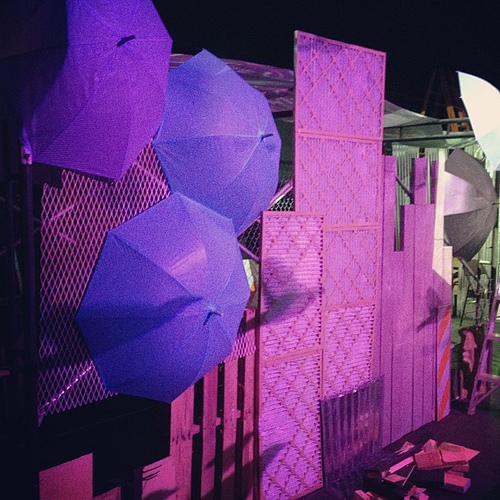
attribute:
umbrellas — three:
[22, 3, 287, 413]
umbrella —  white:
[455, 70, 498, 179]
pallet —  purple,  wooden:
[248, 177, 346, 485]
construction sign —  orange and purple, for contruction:
[434, 304, 451, 420]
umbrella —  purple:
[147, 45, 288, 246]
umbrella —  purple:
[101, 216, 263, 346]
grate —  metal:
[20, 135, 189, 423]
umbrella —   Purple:
[76, 203, 269, 393]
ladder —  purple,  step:
[458, 285, 494, 416]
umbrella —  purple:
[190, 55, 221, 158]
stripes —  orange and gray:
[431, 305, 459, 421]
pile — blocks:
[353, 440, 480, 498]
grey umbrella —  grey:
[463, 69, 499, 171]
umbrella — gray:
[438, 145, 497, 262]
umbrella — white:
[446, 150, 499, 262]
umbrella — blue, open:
[75, 191, 248, 398]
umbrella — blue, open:
[166, 42, 290, 212]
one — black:
[439, 147, 485, 252]